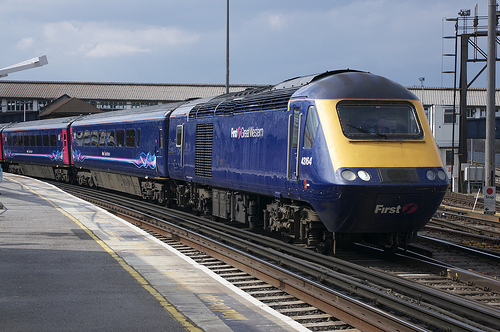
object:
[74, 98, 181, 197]
car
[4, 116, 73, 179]
car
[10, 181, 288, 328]
platform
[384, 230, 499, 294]
track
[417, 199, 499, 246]
track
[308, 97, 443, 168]
train part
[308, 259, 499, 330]
railroad track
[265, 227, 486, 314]
track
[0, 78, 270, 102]
roof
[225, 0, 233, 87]
pole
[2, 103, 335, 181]
side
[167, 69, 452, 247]
cars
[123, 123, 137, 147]
windows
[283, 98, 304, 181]
door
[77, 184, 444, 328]
line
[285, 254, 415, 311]
tracks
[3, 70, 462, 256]
train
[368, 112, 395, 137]
conductor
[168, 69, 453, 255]
train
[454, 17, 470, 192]
pole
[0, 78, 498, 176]
building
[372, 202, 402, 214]
first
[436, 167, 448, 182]
light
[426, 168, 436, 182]
light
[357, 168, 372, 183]
light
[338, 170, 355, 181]
light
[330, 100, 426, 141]
window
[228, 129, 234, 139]
lettering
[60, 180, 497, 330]
track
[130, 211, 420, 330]
rust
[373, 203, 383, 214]
text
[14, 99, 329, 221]
side